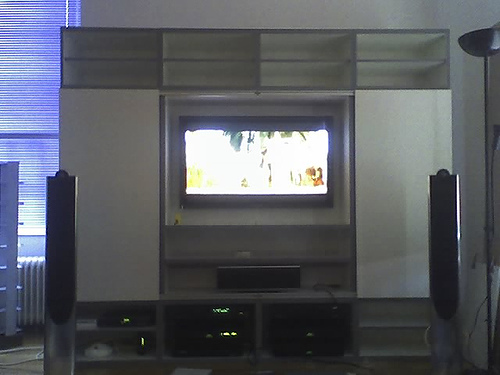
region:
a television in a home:
[53, 6, 407, 312]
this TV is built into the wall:
[158, 86, 352, 230]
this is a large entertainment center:
[46, 17, 463, 356]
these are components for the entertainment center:
[150, 272, 361, 361]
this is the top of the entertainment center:
[49, 18, 466, 98]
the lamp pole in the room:
[449, 18, 499, 263]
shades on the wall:
[4, 3, 84, 261]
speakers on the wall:
[35, 167, 85, 367]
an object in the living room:
[1, 157, 24, 342]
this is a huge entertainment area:
[35, 26, 465, 291]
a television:
[178, 124, 333, 197]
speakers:
[41, 173, 88, 370]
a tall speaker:
[423, 165, 471, 321]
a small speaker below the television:
[218, 266, 299, 286]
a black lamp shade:
[456, 31, 496, 62]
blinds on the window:
[10, 47, 53, 108]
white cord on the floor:
[3, 340, 33, 363]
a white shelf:
[365, 310, 417, 335]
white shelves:
[260, 35, 343, 92]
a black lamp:
[343, 29, 454, 368]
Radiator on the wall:
[18, 256, 47, 330]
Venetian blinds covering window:
[0, 25, 57, 233]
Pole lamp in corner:
[458, 27, 498, 374]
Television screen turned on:
[183, 114, 335, 204]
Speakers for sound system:
[46, 169, 74, 374]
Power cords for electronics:
[1, 348, 46, 365]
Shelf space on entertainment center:
[61, 27, 450, 91]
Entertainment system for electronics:
[61, 26, 450, 357]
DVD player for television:
[218, 265, 299, 291]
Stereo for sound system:
[163, 300, 259, 356]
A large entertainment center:
[45, 8, 481, 373]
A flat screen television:
[165, 101, 344, 218]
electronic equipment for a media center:
[83, 295, 354, 371]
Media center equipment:
[90, 246, 380, 366]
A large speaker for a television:
[38, 165, 83, 374]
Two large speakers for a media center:
[42, 156, 473, 373]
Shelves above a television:
[50, 21, 462, 97]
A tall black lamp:
[453, 24, 499, 374]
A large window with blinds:
[2, 8, 51, 252]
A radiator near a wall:
[14, 253, 42, 332]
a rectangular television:
[175, 114, 336, 208]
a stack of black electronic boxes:
[162, 305, 245, 357]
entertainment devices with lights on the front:
[266, 302, 347, 357]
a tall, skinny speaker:
[43, 169, 75, 374]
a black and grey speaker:
[427, 168, 457, 374]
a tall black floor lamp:
[457, 25, 498, 373]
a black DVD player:
[92, 308, 151, 328]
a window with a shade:
[0, 1, 80, 238]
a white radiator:
[10, 255, 47, 327]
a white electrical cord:
[0, 343, 45, 367]